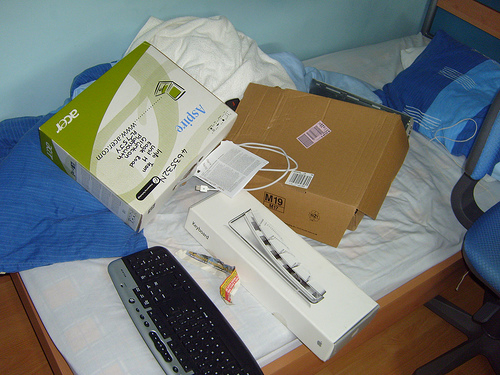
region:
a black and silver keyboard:
[95, 243, 226, 372]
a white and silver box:
[173, 190, 400, 364]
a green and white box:
[27, 47, 254, 206]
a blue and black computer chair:
[419, 82, 496, 369]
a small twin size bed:
[14, 1, 481, 363]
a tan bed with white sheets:
[16, 72, 499, 360]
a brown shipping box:
[216, 85, 399, 272]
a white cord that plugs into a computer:
[168, 131, 320, 206]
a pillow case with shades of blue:
[360, 29, 497, 139]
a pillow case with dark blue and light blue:
[361, 25, 495, 130]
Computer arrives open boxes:
[40, 50, 417, 374]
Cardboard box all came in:
[237, 78, 407, 225]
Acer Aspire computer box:
[38, 62, 234, 201]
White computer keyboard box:
[240, 192, 392, 361]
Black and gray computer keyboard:
[129, 250, 219, 373]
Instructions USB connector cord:
[190, 135, 302, 197]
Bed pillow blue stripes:
[385, 33, 499, 157]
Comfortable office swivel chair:
[451, 83, 499, 368]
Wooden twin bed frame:
[257, 279, 464, 334]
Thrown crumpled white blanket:
[120, 7, 289, 97]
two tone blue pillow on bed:
[359, 33, 497, 170]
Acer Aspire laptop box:
[61, 44, 230, 229]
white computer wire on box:
[184, 131, 309, 197]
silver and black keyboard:
[111, 233, 204, 373]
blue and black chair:
[427, 81, 499, 368]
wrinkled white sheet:
[387, 138, 452, 260]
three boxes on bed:
[62, 53, 401, 340]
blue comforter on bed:
[17, 165, 74, 264]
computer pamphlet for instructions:
[191, 131, 286, 202]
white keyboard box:
[193, 188, 380, 361]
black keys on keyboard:
[128, 268, 191, 316]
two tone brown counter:
[382, 305, 419, 350]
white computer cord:
[222, 128, 299, 191]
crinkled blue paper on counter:
[30, 201, 104, 240]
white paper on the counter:
[47, 277, 143, 374]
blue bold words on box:
[171, 93, 233, 147]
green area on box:
[35, 98, 95, 154]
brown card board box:
[227, 75, 433, 249]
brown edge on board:
[27, 320, 62, 358]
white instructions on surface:
[163, 119, 308, 222]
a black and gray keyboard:
[105, 243, 268, 373]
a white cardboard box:
[182, 185, 381, 364]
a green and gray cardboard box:
[36, 39, 238, 234]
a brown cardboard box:
[224, 77, 412, 249]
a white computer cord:
[191, 138, 301, 197]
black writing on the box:
[261, 190, 288, 207]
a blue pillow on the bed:
[369, 24, 499, 184]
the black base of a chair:
[411, 274, 498, 374]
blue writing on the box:
[171, 98, 207, 134]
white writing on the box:
[51, 107, 81, 135]